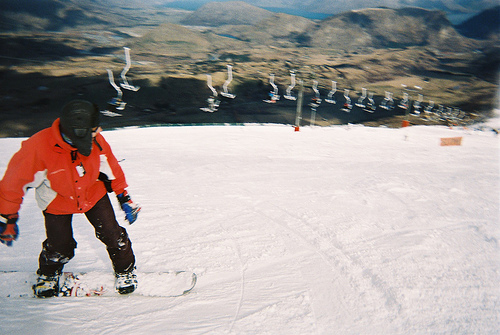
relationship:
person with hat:
[0, 91, 147, 299] [39, 90, 111, 161]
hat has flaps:
[39, 90, 111, 161] [68, 125, 98, 156]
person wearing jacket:
[13, 87, 177, 322] [20, 141, 123, 207]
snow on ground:
[4, 123, 497, 333] [154, 143, 437, 316]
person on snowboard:
[0, 91, 147, 299] [6, 269, 203, 299]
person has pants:
[0, 91, 147, 299] [37, 193, 133, 274]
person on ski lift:
[266, 82, 276, 96] [261, 72, 299, 108]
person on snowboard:
[0, 91, 147, 299] [2, 271, 197, 294]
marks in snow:
[176, 160, 498, 331] [4, 123, 497, 333]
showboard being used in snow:
[1, 266, 207, 297] [4, 123, 497, 333]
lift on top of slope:
[122, 40, 466, 120] [0, 123, 498, 332]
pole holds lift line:
[294, 80, 304, 137] [6, 39, 471, 133]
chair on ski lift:
[97, 96, 127, 120] [49, 44, 491, 124]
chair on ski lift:
[199, 96, 223, 112] [49, 44, 491, 124]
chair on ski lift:
[281, 87, 298, 103] [49, 44, 491, 124]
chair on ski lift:
[339, 99, 355, 115] [49, 44, 491, 124]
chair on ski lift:
[119, 74, 141, 95] [49, 44, 491, 124]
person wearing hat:
[0, 91, 147, 299] [56, 103, 101, 150]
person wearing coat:
[0, 91, 147, 299] [0, 116, 129, 222]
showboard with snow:
[1, 268, 198, 298] [4, 268, 193, 296]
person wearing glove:
[0, 91, 147, 299] [120, 194, 142, 226]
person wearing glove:
[0, 91, 147, 299] [0, 212, 21, 249]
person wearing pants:
[0, 91, 147, 299] [37, 193, 133, 278]